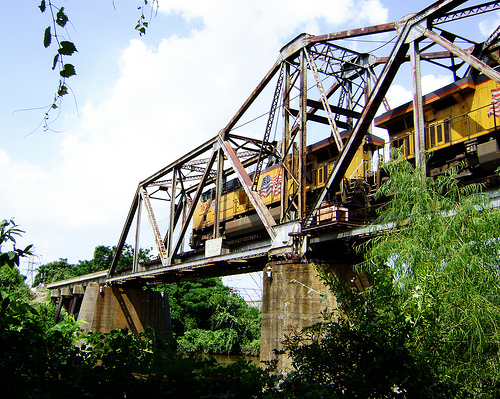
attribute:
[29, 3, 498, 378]
bridge — open, arched, triangle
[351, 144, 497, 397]
bush — large, full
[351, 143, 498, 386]
tree — resting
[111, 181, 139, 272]
bar — metal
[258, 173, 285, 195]
flag — american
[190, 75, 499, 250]
train — yellow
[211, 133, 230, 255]
bar — metal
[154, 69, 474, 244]
train — yellow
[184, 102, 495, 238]
train — large, yellow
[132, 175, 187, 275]
bar — metal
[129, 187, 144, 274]
bar — metal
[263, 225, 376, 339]
pillar — holding up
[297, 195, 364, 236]
platform — metal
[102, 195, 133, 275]
bar — metal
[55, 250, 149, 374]
wooded area — small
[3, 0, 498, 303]
sky — clear, blue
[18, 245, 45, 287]
tower — metal, standing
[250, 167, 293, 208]
flag — american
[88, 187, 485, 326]
bridge — supported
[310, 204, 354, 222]
guard — metal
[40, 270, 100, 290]
bridge — open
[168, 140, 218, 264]
bar — metal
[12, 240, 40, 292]
pole — electrical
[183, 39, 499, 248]
train — yellow